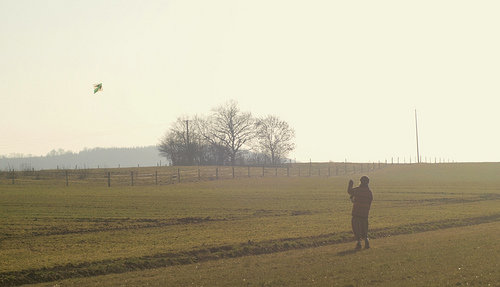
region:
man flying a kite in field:
[72, 60, 375, 262]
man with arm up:
[339, 169, 384, 253]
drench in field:
[1, 235, 312, 280]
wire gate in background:
[6, 149, 470, 185]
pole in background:
[411, 107, 424, 163]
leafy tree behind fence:
[207, 105, 252, 175]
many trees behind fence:
[166, 101, 301, 160]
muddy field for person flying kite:
[12, 167, 395, 259]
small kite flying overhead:
[80, 75, 105, 95]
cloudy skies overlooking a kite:
[6, 6, 494, 107]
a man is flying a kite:
[339, 168, 381, 253]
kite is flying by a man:
[79, 65, 114, 102]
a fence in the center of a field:
[13, 153, 457, 185]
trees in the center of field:
[145, 99, 307, 175]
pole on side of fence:
[407, 99, 427, 168]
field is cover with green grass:
[0, 160, 498, 284]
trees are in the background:
[0, 139, 293, 167]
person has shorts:
[339, 170, 379, 255]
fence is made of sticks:
[1, 156, 461, 187]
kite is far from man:
[68, 69, 396, 259]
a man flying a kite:
[330, 137, 412, 285]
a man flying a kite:
[294, 115, 376, 272]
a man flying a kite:
[310, 165, 370, 285]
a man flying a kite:
[315, 111, 395, 231]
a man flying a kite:
[370, 125, 420, 275]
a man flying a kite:
[330, 157, 382, 258]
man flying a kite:
[284, 119, 379, 250]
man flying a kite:
[330, 164, 385, 270]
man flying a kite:
[328, 106, 356, 276]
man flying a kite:
[344, 137, 373, 277]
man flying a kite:
[345, 121, 397, 281]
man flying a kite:
[358, 140, 384, 266]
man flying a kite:
[330, 200, 371, 276]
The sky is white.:
[162, 3, 342, 68]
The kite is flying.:
[75, 67, 135, 122]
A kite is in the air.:
[80, 65, 117, 100]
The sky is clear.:
[232, 20, 400, 74]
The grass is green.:
[256, 263, 325, 280]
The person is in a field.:
[301, 155, 401, 257]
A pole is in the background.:
[398, 94, 436, 171]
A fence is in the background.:
[57, 165, 232, 200]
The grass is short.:
[92, 208, 317, 285]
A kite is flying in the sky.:
[81, 69, 139, 109]